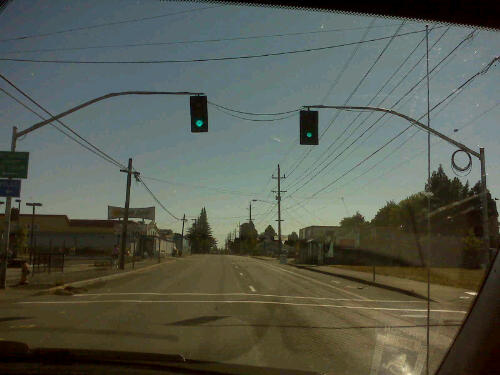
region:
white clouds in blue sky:
[37, 19, 114, 60]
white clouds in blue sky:
[96, 93, 160, 147]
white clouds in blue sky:
[167, 165, 241, 200]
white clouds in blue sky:
[311, 179, 361, 217]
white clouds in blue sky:
[352, 136, 418, 190]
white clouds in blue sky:
[114, 27, 204, 62]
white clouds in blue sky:
[218, 22, 309, 89]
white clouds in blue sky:
[320, 25, 411, 92]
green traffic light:
[173, 85, 218, 135]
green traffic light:
[292, 94, 321, 153]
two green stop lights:
[132, 71, 372, 212]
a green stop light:
[283, 80, 365, 176]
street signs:
[1, 95, 34, 277]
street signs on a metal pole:
[1, 108, 118, 284]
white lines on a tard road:
[155, 233, 320, 365]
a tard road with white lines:
[135, 230, 375, 362]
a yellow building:
[18, 195, 195, 275]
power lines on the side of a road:
[231, 145, 411, 352]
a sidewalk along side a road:
[314, 222, 496, 361]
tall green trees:
[176, 193, 248, 265]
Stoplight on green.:
[298, 103, 319, 143]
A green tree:
[187, 205, 216, 252]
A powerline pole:
[270, 160, 289, 259]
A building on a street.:
[297, 225, 359, 262]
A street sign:
[0, 149, 30, 179]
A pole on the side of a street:
[118, 154, 138, 271]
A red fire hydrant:
[17, 262, 30, 287]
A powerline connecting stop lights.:
[209, 98, 299, 120]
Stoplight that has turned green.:
[299, 103, 321, 145]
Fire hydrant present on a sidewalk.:
[17, 262, 30, 285]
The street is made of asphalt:
[56, 305, 421, 360]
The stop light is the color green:
[184, 88, 213, 138]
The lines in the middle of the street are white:
[80, 287, 434, 318]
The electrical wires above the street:
[16, 5, 383, 72]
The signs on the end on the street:
[0, 141, 32, 202]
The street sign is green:
[1, 144, 35, 179]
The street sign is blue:
[1, 178, 23, 203]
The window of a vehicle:
[28, 58, 418, 331]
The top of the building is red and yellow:
[31, 208, 110, 238]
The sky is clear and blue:
[70, 23, 380, 99]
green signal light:
[181, 108, 207, 142]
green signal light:
[290, 126, 318, 151]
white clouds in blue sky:
[57, 148, 88, 195]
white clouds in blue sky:
[222, 98, 277, 172]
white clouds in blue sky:
[306, 163, 347, 209]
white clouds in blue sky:
[155, 27, 239, 61]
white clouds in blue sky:
[285, 32, 372, 97]